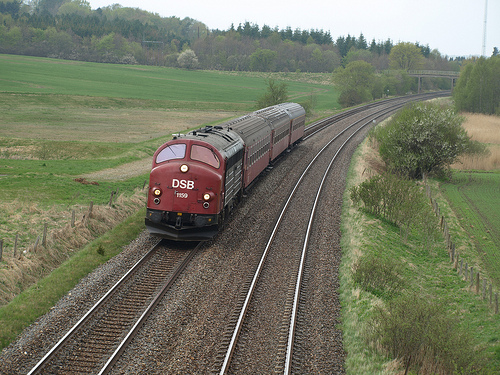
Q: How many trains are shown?
A: 1.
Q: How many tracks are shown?
A: 2.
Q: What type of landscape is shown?
A: Pastoral.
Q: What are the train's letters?
A: DSB.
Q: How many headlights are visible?
A: 2.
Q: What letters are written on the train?
A: DSB.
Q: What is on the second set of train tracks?
A: Nothing.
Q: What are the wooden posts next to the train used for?
A: Fence.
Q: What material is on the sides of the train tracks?
A: Gravel.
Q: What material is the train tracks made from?
A: Metal.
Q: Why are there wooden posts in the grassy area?
A: For a fence.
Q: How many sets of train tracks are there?
A: Two.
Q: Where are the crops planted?
A: Right side of the tracks.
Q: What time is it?
A: Afternoon.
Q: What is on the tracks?
A: A train.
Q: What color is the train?
A: Red.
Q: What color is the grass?
A: Green.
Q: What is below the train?
A: Tracks.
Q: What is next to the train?
A: Grass.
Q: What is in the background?
A: Trees.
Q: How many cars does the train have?
A: Three.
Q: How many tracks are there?
A: Two.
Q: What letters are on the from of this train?
A: DSB.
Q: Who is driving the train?
A: The conductor.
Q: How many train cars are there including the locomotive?
A: 4.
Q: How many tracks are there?
A: 2.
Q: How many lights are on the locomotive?
A: 3.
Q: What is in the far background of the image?
A: Trees.